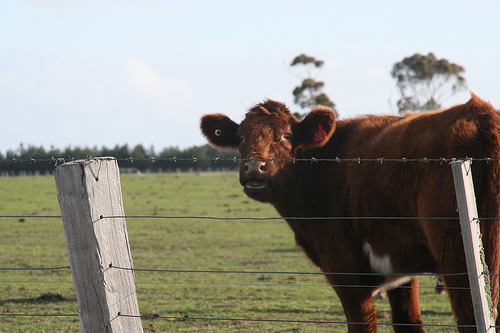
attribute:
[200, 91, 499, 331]
cow — brown, furry, mooing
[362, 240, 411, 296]
patch — white, fur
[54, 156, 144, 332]
post — wooden, grey, thick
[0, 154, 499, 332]
fence — wire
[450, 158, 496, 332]
post — wooden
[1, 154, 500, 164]
wire — barbed, silver, metal, small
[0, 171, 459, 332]
field — green, large, grass, ground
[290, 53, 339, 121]
tree — leafy, tall, green, large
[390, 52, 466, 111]
tree — leafy, tall, green, large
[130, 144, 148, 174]
tree — leafy, tall, green, large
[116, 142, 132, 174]
tree — green, large, leafy, tall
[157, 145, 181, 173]
tree — green, leafy, tall, large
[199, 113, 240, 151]
ear — large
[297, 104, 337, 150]
ear — large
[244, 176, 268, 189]
mouth — open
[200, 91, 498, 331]
fur — long, fluffy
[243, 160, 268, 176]
nose — brown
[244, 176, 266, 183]
lip — brown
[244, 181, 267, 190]
lip — brown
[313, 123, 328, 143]
tag — pink, red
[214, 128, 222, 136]
button — white, black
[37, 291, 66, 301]
pile — droppings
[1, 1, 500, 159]
sky — blue